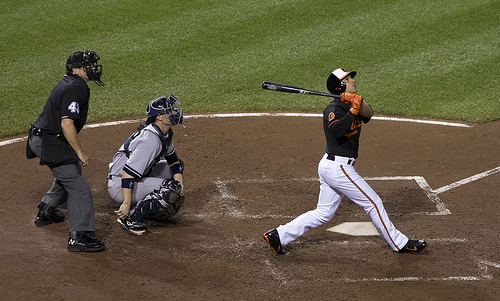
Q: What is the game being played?
A: Baseball.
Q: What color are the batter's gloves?
A: Orange.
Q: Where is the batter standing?
A: Batter's box.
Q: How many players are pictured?
A: Two.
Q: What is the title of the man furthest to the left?
A: Umpire.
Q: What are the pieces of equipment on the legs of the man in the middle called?
A: Guards.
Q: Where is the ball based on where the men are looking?
A: Air.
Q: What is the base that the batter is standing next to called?
A: Home Plate.